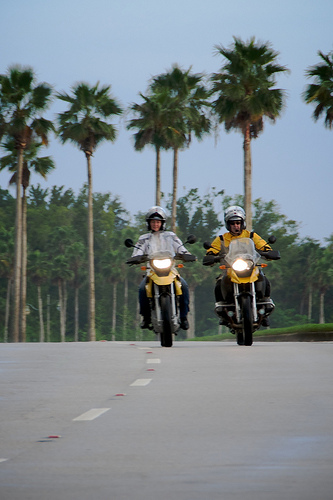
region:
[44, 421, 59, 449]
red reflecters in road between white lines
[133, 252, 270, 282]
motorcycles' headlights are bright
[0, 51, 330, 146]
tall palm trees behind the motorcycles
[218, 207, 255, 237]
man is wearing sunglasses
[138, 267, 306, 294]
motorcycles are bright yellow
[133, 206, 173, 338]
woman driving the motorcycle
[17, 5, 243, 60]
no clouds in blue sky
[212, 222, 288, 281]
man's jacket is yellow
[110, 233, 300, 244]
mirrors on the motorcycles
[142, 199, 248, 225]
helmets are silver with microphones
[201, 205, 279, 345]
a man riding a motorcycle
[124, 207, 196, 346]
a person riding a motorcycle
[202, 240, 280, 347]
a man's motorcycle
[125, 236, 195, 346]
somebody's motorcycle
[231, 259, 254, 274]
headlight of a man's motorcycle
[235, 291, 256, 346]
front tire of a man's motorcycle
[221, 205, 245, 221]
a man's motorcycle helmet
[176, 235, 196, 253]
left mirror of a motorcycle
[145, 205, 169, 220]
a woman's motorcycle helmet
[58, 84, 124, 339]
a tall palm tree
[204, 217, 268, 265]
the coat is yellow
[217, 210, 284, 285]
the coat is yellow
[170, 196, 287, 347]
the coat is yellow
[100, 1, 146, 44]
part of the sky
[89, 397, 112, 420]
part of a white line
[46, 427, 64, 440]
part of a red thing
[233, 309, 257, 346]
part of a wheel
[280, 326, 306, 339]
edge of a road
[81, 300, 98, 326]
stem of a tree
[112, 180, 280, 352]
two riders on separate motorcycles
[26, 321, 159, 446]
riders on one side of white lines and reflectors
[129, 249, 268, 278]
headlights on for both bikes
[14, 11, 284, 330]
tall palm trees behind bikers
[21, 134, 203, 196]
grayish-blue sky between trees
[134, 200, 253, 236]
both bikers wearing helmets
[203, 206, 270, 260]
biker in yellow jacket wearing sunglasses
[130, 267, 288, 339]
both riders wearing dark pants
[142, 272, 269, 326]
metal and vertical supports on front of motorcycles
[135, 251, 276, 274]
orange signal lights not in use